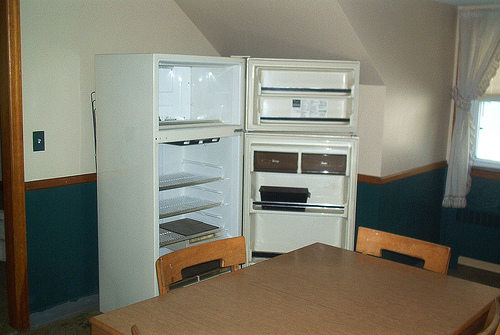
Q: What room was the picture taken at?
A: It was taken at the kitchen.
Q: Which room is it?
A: It is a kitchen.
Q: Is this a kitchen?
A: Yes, it is a kitchen.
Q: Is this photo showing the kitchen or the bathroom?
A: It is showing the kitchen.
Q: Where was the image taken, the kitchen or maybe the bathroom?
A: It was taken at the kitchen.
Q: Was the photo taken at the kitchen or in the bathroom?
A: It was taken at the kitchen.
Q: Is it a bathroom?
A: No, it is a kitchen.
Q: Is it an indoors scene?
A: Yes, it is indoors.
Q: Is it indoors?
A: Yes, it is indoors.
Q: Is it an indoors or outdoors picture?
A: It is indoors.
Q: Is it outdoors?
A: No, it is indoors.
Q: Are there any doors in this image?
A: Yes, there is a door.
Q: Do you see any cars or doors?
A: Yes, there is a door.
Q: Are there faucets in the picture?
A: No, there are no faucets.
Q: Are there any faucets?
A: No, there are no faucets.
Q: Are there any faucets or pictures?
A: No, there are no faucets or pictures.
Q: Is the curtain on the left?
A: No, the curtain is on the right of the image.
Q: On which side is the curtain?
A: The curtain is on the right of the image.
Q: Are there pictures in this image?
A: No, there are no pictures.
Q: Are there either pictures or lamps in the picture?
A: No, there are no pictures or lamps.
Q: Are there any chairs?
A: Yes, there is a chair.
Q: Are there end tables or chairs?
A: Yes, there is a chair.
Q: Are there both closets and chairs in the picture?
A: No, there is a chair but no closets.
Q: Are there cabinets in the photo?
A: No, there are no cabinets.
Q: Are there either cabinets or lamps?
A: No, there are no cabinets or lamps.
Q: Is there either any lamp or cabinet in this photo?
A: No, there are no cabinets or lamps.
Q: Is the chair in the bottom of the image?
A: Yes, the chair is in the bottom of the image.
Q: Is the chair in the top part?
A: No, the chair is in the bottom of the image.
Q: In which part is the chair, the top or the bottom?
A: The chair is in the bottom of the image.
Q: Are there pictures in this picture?
A: No, there are no pictures.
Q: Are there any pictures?
A: No, there are no pictures.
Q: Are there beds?
A: No, there are no beds.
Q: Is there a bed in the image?
A: No, there are no beds.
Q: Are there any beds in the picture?
A: No, there are no beds.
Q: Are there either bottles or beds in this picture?
A: No, there are no beds or bottles.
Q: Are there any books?
A: No, there are no books.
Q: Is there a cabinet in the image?
A: No, there are no cabinets.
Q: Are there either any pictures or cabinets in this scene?
A: No, there are no cabinets or pictures.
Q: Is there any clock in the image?
A: No, there are no clocks.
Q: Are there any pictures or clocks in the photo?
A: No, there are no clocks or pictures.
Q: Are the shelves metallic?
A: Yes, the shelves are metallic.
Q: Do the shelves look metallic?
A: Yes, the shelves are metallic.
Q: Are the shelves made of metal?
A: Yes, the shelves are made of metal.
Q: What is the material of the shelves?
A: The shelves are made of metal.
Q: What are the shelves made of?
A: The shelves are made of metal.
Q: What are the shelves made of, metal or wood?
A: The shelves are made of metal.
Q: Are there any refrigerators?
A: Yes, there is a refrigerator.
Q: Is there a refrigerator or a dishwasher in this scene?
A: Yes, there is a refrigerator.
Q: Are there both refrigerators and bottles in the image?
A: No, there is a refrigerator but no bottles.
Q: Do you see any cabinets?
A: No, there are no cabinets.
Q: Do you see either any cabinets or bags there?
A: No, there are no cabinets or bags.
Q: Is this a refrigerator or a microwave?
A: This is a refrigerator.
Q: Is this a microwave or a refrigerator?
A: This is a refrigerator.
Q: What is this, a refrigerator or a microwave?
A: This is a refrigerator.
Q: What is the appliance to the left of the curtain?
A: The appliance is a refrigerator.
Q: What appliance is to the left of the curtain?
A: The appliance is a refrigerator.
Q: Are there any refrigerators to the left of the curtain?
A: Yes, there is a refrigerator to the left of the curtain.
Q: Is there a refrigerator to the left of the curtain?
A: Yes, there is a refrigerator to the left of the curtain.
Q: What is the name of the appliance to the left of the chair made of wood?
A: The appliance is a refrigerator.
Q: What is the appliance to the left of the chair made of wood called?
A: The appliance is a refrigerator.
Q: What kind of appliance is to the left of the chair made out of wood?
A: The appliance is a refrigerator.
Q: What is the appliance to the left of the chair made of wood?
A: The appliance is a refrigerator.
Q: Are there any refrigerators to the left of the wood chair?
A: Yes, there is a refrigerator to the left of the chair.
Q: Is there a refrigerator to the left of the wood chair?
A: Yes, there is a refrigerator to the left of the chair.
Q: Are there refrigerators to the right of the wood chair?
A: No, the refrigerator is to the left of the chair.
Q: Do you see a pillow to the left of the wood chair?
A: No, there is a refrigerator to the left of the chair.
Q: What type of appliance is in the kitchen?
A: The appliance is a refrigerator.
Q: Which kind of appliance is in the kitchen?
A: The appliance is a refrigerator.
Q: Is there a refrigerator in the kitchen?
A: Yes, there is a refrigerator in the kitchen.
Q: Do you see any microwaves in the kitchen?
A: No, there is a refrigerator in the kitchen.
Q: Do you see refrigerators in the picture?
A: Yes, there is a refrigerator.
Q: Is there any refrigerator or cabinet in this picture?
A: Yes, there is a refrigerator.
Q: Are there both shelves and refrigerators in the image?
A: Yes, there are both a refrigerator and a shelf.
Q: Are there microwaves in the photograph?
A: No, there are no microwaves.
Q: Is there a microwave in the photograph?
A: No, there are no microwaves.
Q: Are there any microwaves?
A: No, there are no microwaves.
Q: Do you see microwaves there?
A: No, there are no microwaves.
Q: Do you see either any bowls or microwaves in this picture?
A: No, there are no microwaves or bowls.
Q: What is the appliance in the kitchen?
A: The appliance is a refrigerator.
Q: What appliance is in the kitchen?
A: The appliance is a refrigerator.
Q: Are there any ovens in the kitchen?
A: No, there is a refrigerator in the kitchen.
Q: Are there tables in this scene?
A: Yes, there is a table.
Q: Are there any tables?
A: Yes, there is a table.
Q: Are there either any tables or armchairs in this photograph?
A: Yes, there is a table.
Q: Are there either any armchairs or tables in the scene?
A: Yes, there is a table.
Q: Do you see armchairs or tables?
A: Yes, there is a table.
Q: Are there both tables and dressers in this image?
A: No, there is a table but no dressers.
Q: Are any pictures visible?
A: No, there are no pictures.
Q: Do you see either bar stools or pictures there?
A: No, there are no pictures or bar stools.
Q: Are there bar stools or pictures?
A: No, there are no pictures or bar stools.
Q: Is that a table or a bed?
A: That is a table.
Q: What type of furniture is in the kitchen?
A: The piece of furniture is a table.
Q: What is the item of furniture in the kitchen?
A: The piece of furniture is a table.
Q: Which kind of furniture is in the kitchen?
A: The piece of furniture is a table.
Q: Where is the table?
A: The table is in the kitchen.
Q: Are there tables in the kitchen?
A: Yes, there is a table in the kitchen.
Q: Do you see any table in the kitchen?
A: Yes, there is a table in the kitchen.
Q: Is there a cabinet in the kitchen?
A: No, there is a table in the kitchen.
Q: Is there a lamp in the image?
A: No, there are no lamps.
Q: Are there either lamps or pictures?
A: No, there are no lamps or pictures.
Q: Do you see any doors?
A: Yes, there is a door.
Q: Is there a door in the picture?
A: Yes, there is a door.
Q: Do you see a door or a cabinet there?
A: Yes, there is a door.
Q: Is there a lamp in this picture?
A: No, there are no lamps.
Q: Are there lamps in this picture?
A: No, there are no lamps.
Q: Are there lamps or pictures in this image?
A: No, there are no lamps or pictures.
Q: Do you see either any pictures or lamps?
A: No, there are no lamps or pictures.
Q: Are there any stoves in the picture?
A: No, there are no stoves.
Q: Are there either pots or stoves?
A: No, there are no stoves or pots.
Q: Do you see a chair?
A: Yes, there is a chair.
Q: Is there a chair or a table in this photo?
A: Yes, there is a chair.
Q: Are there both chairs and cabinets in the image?
A: No, there is a chair but no cabinets.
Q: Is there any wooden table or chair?
A: Yes, there is a wood chair.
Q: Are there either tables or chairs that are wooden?
A: Yes, the chair is wooden.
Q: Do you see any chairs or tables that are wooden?
A: Yes, the chair is wooden.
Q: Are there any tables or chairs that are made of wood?
A: Yes, the chair is made of wood.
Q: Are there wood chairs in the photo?
A: Yes, there is a wood chair.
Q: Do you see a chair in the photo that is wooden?
A: Yes, there is a chair that is wooden.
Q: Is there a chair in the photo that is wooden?
A: Yes, there is a chair that is wooden.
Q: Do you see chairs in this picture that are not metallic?
A: Yes, there is a wooden chair.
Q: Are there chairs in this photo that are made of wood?
A: Yes, there is a chair that is made of wood.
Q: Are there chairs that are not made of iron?
A: Yes, there is a chair that is made of wood.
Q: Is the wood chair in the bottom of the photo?
A: Yes, the chair is in the bottom of the image.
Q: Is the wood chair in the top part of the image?
A: No, the chair is in the bottom of the image.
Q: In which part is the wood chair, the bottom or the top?
A: The chair is in the bottom of the image.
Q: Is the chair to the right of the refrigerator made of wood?
A: Yes, the chair is made of wood.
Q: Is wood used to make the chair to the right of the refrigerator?
A: Yes, the chair is made of wood.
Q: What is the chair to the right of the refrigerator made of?
A: The chair is made of wood.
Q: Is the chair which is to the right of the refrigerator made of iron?
A: No, the chair is made of wood.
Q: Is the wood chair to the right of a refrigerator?
A: Yes, the chair is to the right of a refrigerator.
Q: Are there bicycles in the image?
A: No, there are no bicycles.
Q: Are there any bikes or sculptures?
A: No, there are no bikes or sculptures.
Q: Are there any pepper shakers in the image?
A: No, there are no pepper shakers.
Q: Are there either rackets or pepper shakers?
A: No, there are no pepper shakers or rackets.